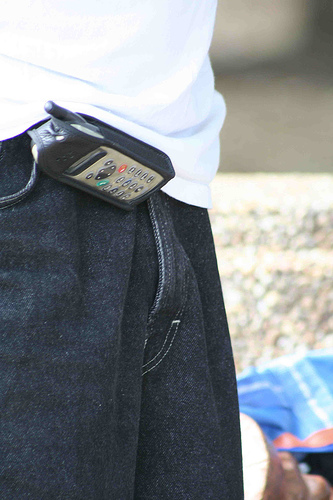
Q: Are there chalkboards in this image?
A: No, there are no chalkboards.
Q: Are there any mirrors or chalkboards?
A: No, there are no chalkboards or mirrors.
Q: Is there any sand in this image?
A: Yes, there is sand.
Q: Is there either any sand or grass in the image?
A: Yes, there is sand.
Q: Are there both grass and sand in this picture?
A: No, there is sand but no grass.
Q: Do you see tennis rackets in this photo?
A: No, there are no tennis rackets.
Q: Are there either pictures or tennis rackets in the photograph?
A: No, there are no tennis rackets or pictures.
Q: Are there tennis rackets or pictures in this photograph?
A: No, there are no tennis rackets or pictures.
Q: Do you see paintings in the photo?
A: No, there are no paintings.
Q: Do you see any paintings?
A: No, there are no paintings.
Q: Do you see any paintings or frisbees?
A: No, there are no paintings or frisbees.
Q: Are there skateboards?
A: No, there are no skateboards.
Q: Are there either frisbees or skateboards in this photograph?
A: No, there are no skateboards or frisbees.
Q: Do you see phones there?
A: Yes, there is a phone.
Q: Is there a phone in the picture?
A: Yes, there is a phone.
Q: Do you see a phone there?
A: Yes, there is a phone.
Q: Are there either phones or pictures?
A: Yes, there is a phone.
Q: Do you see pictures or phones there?
A: Yes, there is a phone.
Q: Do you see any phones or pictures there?
A: Yes, there is a phone.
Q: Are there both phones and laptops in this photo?
A: No, there is a phone but no laptops.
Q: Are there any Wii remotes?
A: No, there are no Wii remotes.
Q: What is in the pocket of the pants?
A: The phone is in the pocket.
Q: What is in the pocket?
A: The phone is in the pocket.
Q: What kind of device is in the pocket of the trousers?
A: The device is a phone.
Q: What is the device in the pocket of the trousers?
A: The device is a phone.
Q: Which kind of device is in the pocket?
A: The device is a phone.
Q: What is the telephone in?
A: The telephone is in the pocket.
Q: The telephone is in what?
A: The telephone is in the pocket.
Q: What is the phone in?
A: The telephone is in the pocket.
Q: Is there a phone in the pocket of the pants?
A: Yes, there is a phone in the pocket.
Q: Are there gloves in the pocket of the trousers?
A: No, there is a phone in the pocket.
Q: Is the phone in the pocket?
A: Yes, the phone is in the pocket.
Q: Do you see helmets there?
A: No, there are no helmets.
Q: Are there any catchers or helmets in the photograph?
A: No, there are no helmets or catchers.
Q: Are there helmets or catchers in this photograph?
A: No, there are no helmets or catchers.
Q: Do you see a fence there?
A: No, there are no fences.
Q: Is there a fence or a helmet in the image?
A: No, there are no fences or helmets.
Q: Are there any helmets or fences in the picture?
A: No, there are no fences or helmets.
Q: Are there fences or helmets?
A: No, there are no fences or helmets.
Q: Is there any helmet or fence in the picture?
A: No, there are no fences or helmets.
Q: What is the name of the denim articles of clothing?
A: The clothing items are pants.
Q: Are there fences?
A: No, there are no fences.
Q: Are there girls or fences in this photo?
A: No, there are no fences or girls.